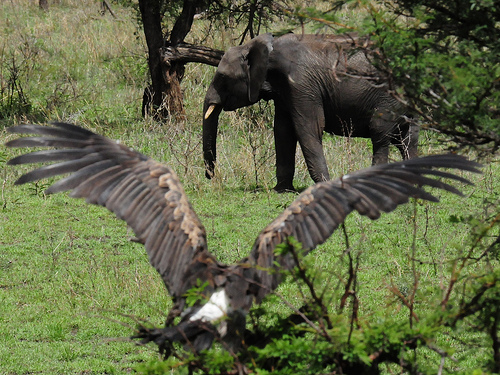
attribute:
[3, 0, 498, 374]
grass — green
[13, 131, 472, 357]
bird —  hunting, afraid, dark colored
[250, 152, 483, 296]
wing — up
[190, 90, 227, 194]
trunk — thick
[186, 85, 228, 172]
trunk — long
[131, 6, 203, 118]
tree — large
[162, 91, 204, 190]
bush — dead, growing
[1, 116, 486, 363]
hawk — flying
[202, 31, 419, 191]
elephant — walking around, walking, big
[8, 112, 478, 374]
bird —  take off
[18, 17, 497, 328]
animals — enjoying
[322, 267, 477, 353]
brush — overgrown 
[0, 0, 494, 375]
weeds — white, brown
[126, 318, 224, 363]
tail — black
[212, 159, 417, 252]
wing — outstretched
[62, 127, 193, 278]
wing — outstretched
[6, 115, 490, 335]
predator bird — large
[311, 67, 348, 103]
skin — wrinkled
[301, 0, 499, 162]
bush — overgrown 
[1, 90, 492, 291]
wingspan — long